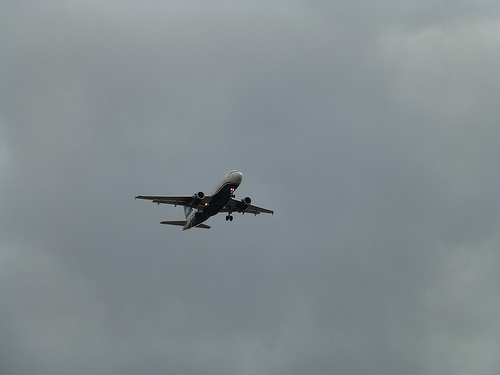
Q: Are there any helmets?
A: No, there are no helmets.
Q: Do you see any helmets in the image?
A: No, there are no helmets.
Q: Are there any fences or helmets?
A: No, there are no helmets or fences.